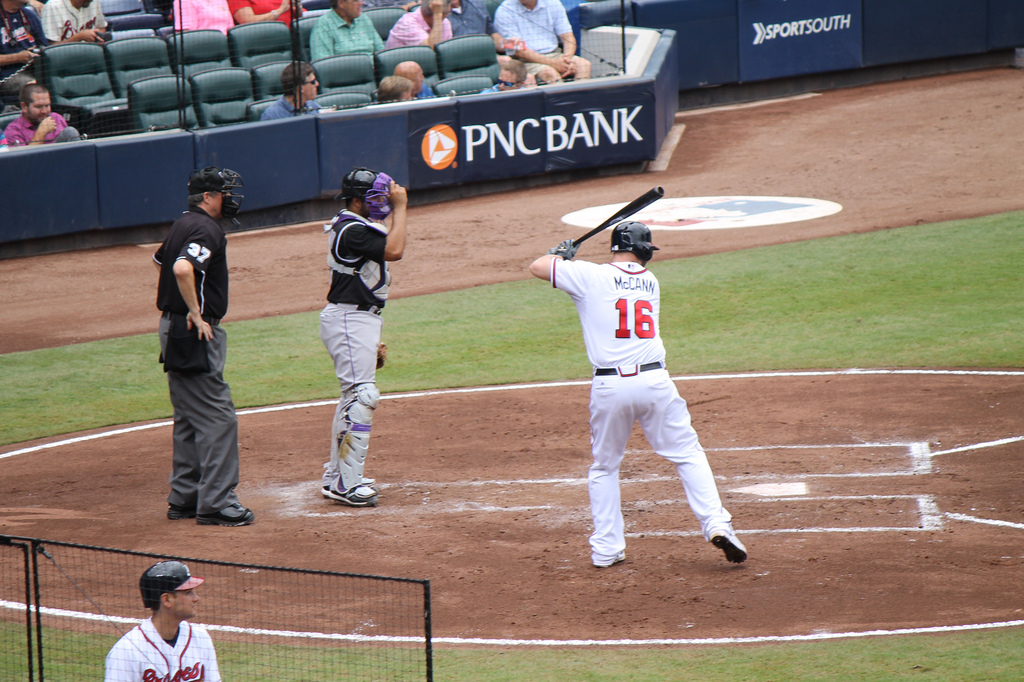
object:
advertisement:
[396, 81, 665, 188]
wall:
[6, 130, 698, 232]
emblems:
[540, 171, 848, 252]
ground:
[335, 145, 992, 321]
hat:
[135, 545, 211, 598]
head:
[115, 536, 209, 619]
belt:
[587, 359, 681, 385]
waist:
[587, 338, 678, 394]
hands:
[167, 305, 217, 345]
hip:
[153, 282, 232, 371]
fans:
[2, 1, 626, 118]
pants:
[544, 350, 759, 562]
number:
[635, 292, 662, 348]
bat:
[547, 180, 682, 258]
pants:
[308, 290, 401, 507]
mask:
[359, 169, 392, 222]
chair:
[127, 70, 201, 135]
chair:
[230, 20, 294, 73]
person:
[398, 59, 440, 103]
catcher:
[297, 155, 404, 521]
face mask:
[357, 175, 407, 215]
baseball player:
[519, 170, 786, 600]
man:
[519, 179, 785, 599]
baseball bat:
[529, 179, 683, 275]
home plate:
[741, 482, 817, 513]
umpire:
[146, 163, 259, 522]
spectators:
[20, 7, 582, 109]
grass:
[864, 236, 980, 332]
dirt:
[782, 381, 936, 451]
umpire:
[157, 150, 283, 514]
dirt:
[851, 377, 967, 574]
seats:
[24, 26, 342, 115]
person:
[502, 9, 600, 94]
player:
[535, 166, 806, 597]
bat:
[551, 158, 667, 265]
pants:
[134, 316, 279, 537]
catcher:
[326, 154, 442, 498]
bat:
[566, 190, 667, 262]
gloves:
[532, 251, 589, 280]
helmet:
[132, 553, 217, 614]